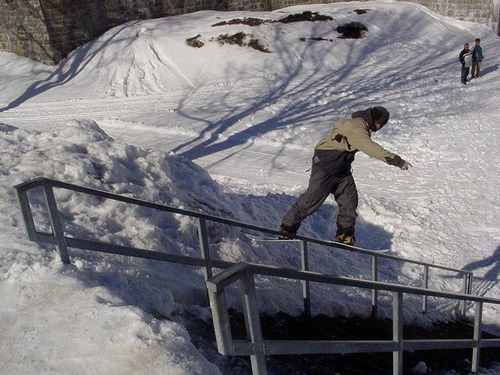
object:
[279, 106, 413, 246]
man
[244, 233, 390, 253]
snowboard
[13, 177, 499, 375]
railing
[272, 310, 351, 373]
stairs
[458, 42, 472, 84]
people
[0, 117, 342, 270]
pile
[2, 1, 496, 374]
snow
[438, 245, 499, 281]
shadow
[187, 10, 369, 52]
dirt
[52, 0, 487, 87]
hill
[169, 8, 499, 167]
shadow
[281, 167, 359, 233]
pants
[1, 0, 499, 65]
wall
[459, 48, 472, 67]
jacket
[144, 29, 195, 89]
tracks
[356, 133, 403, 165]
arm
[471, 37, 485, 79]
person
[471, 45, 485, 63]
jacket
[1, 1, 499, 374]
ground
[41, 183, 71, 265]
poles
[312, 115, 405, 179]
jacket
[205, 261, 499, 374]
part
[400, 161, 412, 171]
hand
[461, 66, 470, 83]
pants